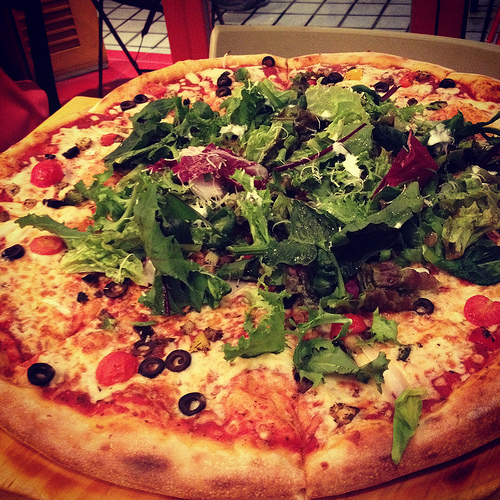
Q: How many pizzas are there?
A: One.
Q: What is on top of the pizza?
A: Salad.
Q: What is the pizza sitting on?
A: The table.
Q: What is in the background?
A: A tile floor.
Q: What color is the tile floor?
A: White.